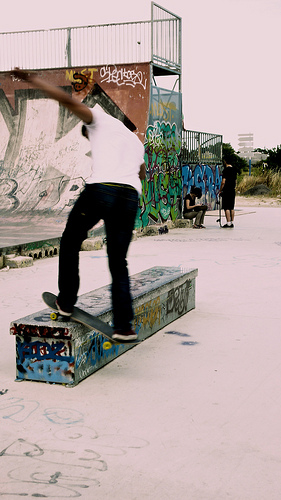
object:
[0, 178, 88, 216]
graffiti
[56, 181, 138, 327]
pant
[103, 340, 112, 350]
wheel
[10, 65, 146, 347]
skateboarder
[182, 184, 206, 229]
person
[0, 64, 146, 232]
ramp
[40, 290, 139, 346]
skateboard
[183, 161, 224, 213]
wall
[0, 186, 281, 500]
ground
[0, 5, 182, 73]
rail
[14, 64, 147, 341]
man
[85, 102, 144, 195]
shirt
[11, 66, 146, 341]
boy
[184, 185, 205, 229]
girl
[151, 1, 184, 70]
post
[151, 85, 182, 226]
gate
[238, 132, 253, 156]
sign